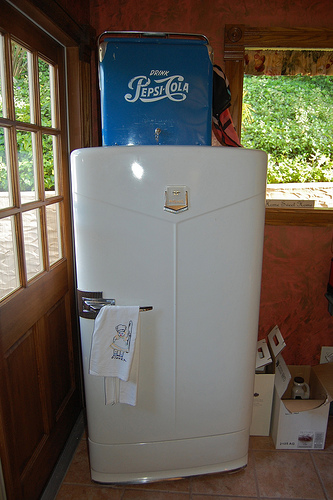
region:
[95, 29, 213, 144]
Blue Pepsi Cola box on the fridge.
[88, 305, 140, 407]
A white hand towel on the fridge with a person on it.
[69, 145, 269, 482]
An old style white fridge.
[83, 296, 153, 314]
A silver handle of a fridge.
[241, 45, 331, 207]
A glass window behind a fridge.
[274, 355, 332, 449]
Open box with a brown lid jug inside.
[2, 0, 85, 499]
A brown door with many window panes.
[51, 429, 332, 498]
A tan tiled floor.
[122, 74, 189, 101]
A white cursive Pepsi Cola.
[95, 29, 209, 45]
A long silver handle on a blue pepsi box.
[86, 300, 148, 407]
Towel on handle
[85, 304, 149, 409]
Towel is on handle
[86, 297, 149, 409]
Towel on door handle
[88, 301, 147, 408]
Towel is on door handle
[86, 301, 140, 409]
White towel on handle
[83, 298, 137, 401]
White towel is on handle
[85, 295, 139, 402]
White towel is on door handle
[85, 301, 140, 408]
White towel on door handle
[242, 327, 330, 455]
Boxes on the floor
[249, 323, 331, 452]
Boxes are on the floor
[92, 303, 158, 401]
the towel is white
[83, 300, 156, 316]
the handle is silver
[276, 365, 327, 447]
the cartoon is opened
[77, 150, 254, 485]
the fridge is white in color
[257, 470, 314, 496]
the floor is tiled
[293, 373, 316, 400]
bottle is in the cartoon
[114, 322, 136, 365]
image is on the towel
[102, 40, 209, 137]
the blue container is on the fridge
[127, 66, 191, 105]
pepsi cola is written in the container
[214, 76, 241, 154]
red and black clothing is on the fridge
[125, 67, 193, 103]
a white logo on blue cooler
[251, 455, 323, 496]
beige tile on the floor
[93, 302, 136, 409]
a dishtowel on the handle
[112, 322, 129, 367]
a cartoon on the dish towel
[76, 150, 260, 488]
an white antique refridgerator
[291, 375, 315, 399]
a bottle of brown sauce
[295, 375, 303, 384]
a black cap on the bottle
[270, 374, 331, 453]
a white cardboard box on the floor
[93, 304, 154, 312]
the metal refrigerator door handle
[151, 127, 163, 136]
a spout on a blue cooler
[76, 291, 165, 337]
a silver handle of the refigerator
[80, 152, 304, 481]
white color refrigerator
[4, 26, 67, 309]
wooden frame window with glass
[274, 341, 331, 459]
white color bottle in the box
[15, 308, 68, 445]
brown color wooden plywood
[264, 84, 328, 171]
plants with leaves outside the building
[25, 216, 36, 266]
sand outside the building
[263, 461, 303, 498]
brown color floor tiles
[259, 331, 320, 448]
cardboard boxes near the refrigerator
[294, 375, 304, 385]
lid of the bottle